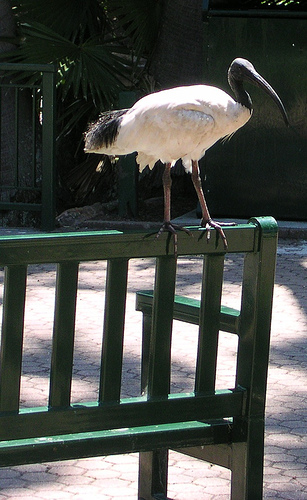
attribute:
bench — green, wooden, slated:
[21, 251, 305, 460]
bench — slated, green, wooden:
[15, 228, 276, 475]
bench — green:
[18, 231, 300, 461]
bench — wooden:
[8, 227, 293, 434]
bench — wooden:
[3, 231, 274, 419]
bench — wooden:
[16, 246, 253, 455]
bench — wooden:
[35, 249, 280, 491]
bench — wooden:
[7, 231, 207, 439]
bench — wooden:
[51, 222, 294, 454]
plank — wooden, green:
[95, 251, 151, 423]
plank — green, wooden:
[132, 252, 216, 396]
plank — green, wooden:
[195, 251, 223, 394]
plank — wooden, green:
[147, 256, 177, 397]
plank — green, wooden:
[98, 258, 130, 399]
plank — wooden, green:
[48, 264, 83, 411]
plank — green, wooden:
[2, 266, 29, 412]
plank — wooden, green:
[137, 287, 242, 334]